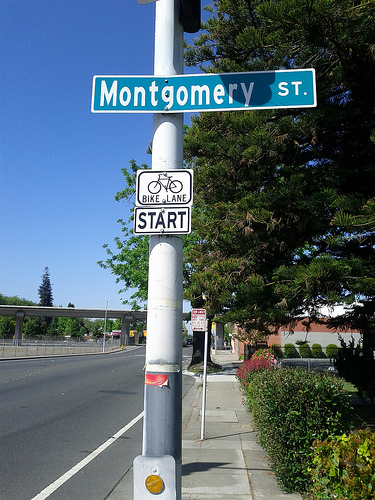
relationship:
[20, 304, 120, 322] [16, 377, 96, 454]
overpass above road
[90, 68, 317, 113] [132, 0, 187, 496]
sign on metal pole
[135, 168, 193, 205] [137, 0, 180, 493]
sign on pole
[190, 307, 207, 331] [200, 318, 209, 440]
sign on pole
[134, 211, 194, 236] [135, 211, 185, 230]
sign that says start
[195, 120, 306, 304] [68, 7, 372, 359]
green leaves on tree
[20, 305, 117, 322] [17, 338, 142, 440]
overpass over street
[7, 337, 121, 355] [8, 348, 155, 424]
fence on side street